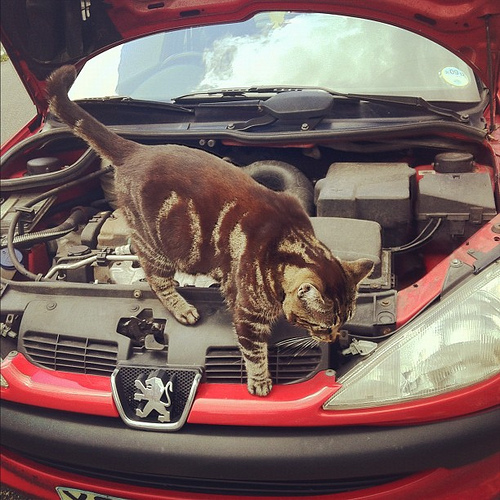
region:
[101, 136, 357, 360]
Cat on a car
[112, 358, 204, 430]
Car insiglia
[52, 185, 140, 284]
Engine of a car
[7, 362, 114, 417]
White color painting of the car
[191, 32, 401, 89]
Reflection of the clouded sky on the windshield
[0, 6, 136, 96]
Open bonnet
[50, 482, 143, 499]
Portion of the number plate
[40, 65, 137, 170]
Long tail of a cat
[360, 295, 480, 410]
Head lamp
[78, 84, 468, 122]
Windshield wipers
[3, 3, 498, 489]
a painted red car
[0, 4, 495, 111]
an open red car hood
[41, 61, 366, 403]
a two toned brown cat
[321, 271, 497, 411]
a car's driver side headlight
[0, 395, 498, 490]
a black car bumper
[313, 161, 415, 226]
a grey plastic engine part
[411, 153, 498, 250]
a grey plastic engine part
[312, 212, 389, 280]
a grey plastic engine part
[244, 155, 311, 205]
a grey plastic engine part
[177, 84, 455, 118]
a windshield wiper blade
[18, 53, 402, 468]
Kitty in the engine compartment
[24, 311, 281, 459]
Lion logo on car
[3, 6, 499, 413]
Hood is up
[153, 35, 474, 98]
Reflection in windshield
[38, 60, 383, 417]
Brown and tan striped cat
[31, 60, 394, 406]
Being careful not to fall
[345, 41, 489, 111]
Sticker inside of windshield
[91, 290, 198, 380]
Latch to keep hood closed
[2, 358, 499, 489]
Black rubber bumper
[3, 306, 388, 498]
Grill to cool the radiator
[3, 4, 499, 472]
a cat standing on a car engine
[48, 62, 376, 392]
a brown stripped cat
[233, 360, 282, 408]
a cat paw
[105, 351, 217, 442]
a car hood ornament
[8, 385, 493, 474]
a car bumper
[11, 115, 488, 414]
a car engine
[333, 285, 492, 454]
a headlight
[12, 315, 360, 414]
a car grill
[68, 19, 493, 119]
a car windshield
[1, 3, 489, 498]
a red car with a cat on it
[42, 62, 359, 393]
cat standing on car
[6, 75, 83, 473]
red car with open hood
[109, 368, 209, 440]
gray Peugeot car symbol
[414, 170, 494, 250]
closed car fuse box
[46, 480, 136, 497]
licence plate on car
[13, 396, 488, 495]
front of red car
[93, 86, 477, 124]
windshield wipers on car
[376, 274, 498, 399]
left headlight on car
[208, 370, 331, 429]
cat's paw on the bumper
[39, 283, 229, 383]
cat's paw on the grill